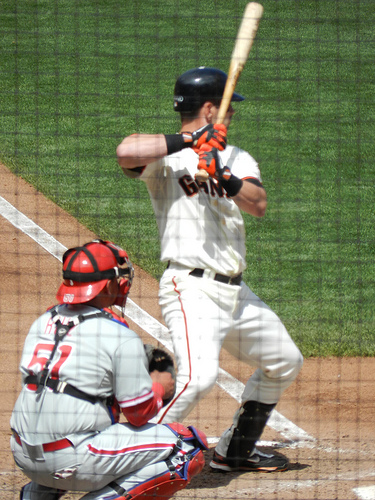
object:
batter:
[116, 70, 307, 477]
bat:
[196, 1, 266, 186]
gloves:
[189, 119, 229, 181]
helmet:
[173, 66, 248, 114]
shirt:
[142, 142, 268, 283]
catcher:
[9, 236, 214, 499]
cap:
[50, 238, 138, 308]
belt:
[5, 434, 76, 457]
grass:
[3, 1, 374, 367]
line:
[0, 195, 318, 444]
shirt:
[5, 300, 156, 447]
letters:
[25, 314, 72, 398]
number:
[22, 342, 73, 395]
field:
[0, 3, 373, 495]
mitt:
[142, 342, 182, 410]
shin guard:
[227, 397, 278, 466]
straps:
[24, 306, 106, 409]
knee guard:
[177, 418, 213, 480]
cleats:
[206, 446, 294, 477]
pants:
[149, 263, 307, 460]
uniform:
[137, 140, 305, 452]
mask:
[117, 251, 136, 307]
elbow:
[113, 140, 134, 163]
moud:
[188, 427, 374, 495]